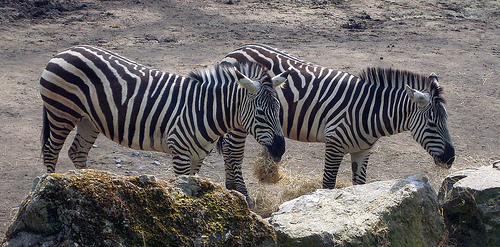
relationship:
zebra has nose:
[31, 47, 283, 188] [269, 135, 288, 159]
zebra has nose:
[220, 45, 455, 189] [436, 146, 455, 170]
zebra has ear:
[31, 47, 283, 188] [236, 71, 256, 91]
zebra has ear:
[31, 47, 283, 188] [273, 66, 297, 85]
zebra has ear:
[220, 45, 455, 189] [402, 86, 429, 107]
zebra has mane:
[31, 47, 283, 188] [196, 68, 254, 77]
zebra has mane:
[220, 45, 455, 189] [367, 68, 426, 90]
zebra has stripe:
[31, 47, 283, 188] [67, 55, 89, 68]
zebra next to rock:
[31, 47, 283, 188] [39, 175, 270, 246]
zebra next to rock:
[31, 47, 283, 188] [282, 174, 444, 246]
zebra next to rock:
[220, 45, 455, 189] [447, 171, 499, 241]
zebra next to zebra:
[31, 47, 283, 188] [220, 45, 455, 189]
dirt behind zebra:
[110, 10, 274, 46] [220, 45, 455, 189]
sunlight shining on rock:
[282, 201, 302, 213] [282, 174, 444, 246]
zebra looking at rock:
[220, 45, 455, 189] [447, 171, 499, 241]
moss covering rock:
[85, 189, 218, 230] [39, 175, 270, 246]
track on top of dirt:
[140, 35, 169, 43] [110, 10, 274, 46]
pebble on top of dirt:
[377, 54, 383, 61] [110, 10, 274, 46]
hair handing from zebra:
[39, 109, 46, 146] [31, 47, 283, 188]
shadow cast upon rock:
[394, 180, 411, 194] [282, 174, 444, 246]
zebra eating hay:
[31, 47, 283, 188] [256, 160, 281, 182]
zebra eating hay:
[220, 45, 455, 189] [431, 167, 451, 178]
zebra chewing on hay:
[31, 47, 283, 188] [256, 160, 281, 182]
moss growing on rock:
[85, 189, 218, 230] [39, 175, 270, 246]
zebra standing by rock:
[31, 47, 283, 188] [39, 175, 270, 246]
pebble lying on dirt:
[23, 167, 31, 179] [110, 10, 274, 46]